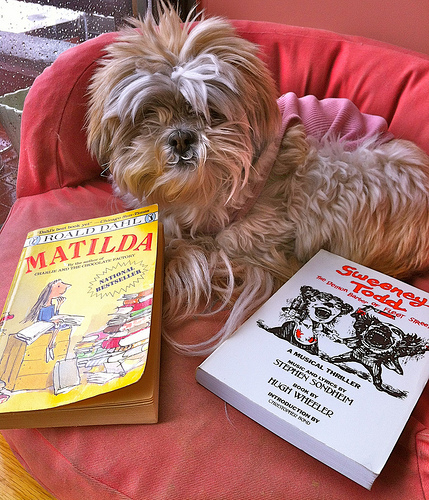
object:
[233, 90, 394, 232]
sweater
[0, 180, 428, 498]
cushion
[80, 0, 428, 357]
dog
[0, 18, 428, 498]
chair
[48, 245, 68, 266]
letter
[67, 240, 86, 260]
letter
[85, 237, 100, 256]
letter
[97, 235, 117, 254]
letter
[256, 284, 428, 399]
image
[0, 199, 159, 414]
yellow cover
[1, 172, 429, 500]
pillow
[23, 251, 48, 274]
letter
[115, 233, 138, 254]
letter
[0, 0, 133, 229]
raindrops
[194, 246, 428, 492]
book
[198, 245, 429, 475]
title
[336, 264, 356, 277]
letter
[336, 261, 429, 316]
writing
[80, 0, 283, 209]
hair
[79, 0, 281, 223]
head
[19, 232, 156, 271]
text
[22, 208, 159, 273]
pages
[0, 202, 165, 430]
book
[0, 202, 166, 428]
cover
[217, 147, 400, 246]
fur